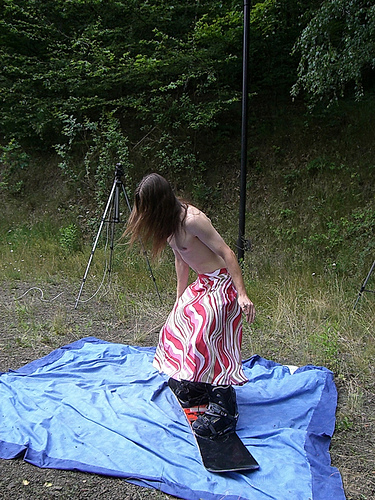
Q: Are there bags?
A: No, there are no bags.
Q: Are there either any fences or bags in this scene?
A: No, there are no bags or fences.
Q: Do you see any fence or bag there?
A: No, there are no bags or fences.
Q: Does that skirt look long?
A: Yes, the skirt is long.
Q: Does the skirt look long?
A: Yes, the skirt is long.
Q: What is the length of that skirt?
A: The skirt is long.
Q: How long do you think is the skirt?
A: The skirt is long.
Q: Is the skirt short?
A: No, the skirt is long.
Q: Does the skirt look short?
A: No, the skirt is long.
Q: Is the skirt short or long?
A: The skirt is long.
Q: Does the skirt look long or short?
A: The skirt is long.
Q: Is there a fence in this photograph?
A: No, there are no fences.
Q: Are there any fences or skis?
A: No, there are no fences or skis.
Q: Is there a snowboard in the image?
A: Yes, there is a snowboard.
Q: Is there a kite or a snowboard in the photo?
A: Yes, there is a snowboard.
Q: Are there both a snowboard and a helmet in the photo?
A: No, there is a snowboard but no helmets.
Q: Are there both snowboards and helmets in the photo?
A: No, there is a snowboard but no helmets.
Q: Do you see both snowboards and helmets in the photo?
A: No, there is a snowboard but no helmets.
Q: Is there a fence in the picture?
A: No, there are no fences.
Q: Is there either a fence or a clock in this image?
A: No, there are no fences or clocks.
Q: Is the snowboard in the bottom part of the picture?
A: Yes, the snowboard is in the bottom of the image.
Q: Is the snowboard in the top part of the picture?
A: No, the snowboard is in the bottom of the image.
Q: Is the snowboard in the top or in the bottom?
A: The snowboard is in the bottom of the image.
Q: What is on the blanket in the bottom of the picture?
A: The snowboard is on the blanket.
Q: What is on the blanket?
A: The snowboard is on the blanket.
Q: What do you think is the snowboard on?
A: The snowboard is on the blanket.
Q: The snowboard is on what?
A: The snowboard is on the blanket.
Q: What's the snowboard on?
A: The snowboard is on the blanket.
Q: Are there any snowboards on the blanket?
A: Yes, there is a snowboard on the blanket.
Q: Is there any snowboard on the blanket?
A: Yes, there is a snowboard on the blanket.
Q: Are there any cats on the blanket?
A: No, there is a snowboard on the blanket.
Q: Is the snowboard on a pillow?
A: No, the snowboard is on the blanket.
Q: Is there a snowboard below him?
A: Yes, there is a snowboard below the man.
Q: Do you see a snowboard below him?
A: Yes, there is a snowboard below the man.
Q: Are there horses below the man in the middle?
A: No, there is a snowboard below the man.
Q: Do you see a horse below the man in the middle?
A: No, there is a snowboard below the man.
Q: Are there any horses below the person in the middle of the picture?
A: No, there is a snowboard below the man.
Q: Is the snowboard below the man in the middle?
A: Yes, the snowboard is below the man.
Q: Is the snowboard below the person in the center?
A: Yes, the snowboard is below the man.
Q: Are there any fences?
A: No, there are no fences.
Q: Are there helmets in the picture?
A: No, there are no helmets.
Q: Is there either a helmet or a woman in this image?
A: No, there are no helmets or women.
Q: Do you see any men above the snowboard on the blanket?
A: Yes, there is a man above the snowboard.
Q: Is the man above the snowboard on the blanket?
A: Yes, the man is above the snow board.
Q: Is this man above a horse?
A: No, the man is above the snow board.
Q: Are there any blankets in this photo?
A: Yes, there is a blanket.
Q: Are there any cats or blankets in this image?
A: Yes, there is a blanket.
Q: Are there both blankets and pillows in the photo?
A: No, there is a blanket but no pillows.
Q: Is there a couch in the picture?
A: No, there are no couches.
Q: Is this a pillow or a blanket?
A: This is a blanket.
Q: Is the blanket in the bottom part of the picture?
A: Yes, the blanket is in the bottom of the image.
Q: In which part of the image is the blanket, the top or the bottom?
A: The blanket is in the bottom of the image.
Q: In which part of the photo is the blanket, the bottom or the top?
A: The blanket is in the bottom of the image.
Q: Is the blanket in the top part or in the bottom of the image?
A: The blanket is in the bottom of the image.